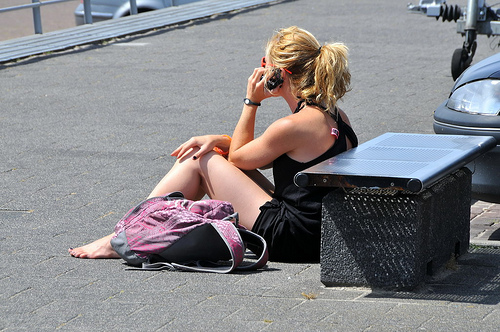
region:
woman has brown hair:
[254, 27, 365, 114]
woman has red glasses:
[250, 55, 294, 85]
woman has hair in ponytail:
[307, 42, 365, 135]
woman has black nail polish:
[170, 122, 227, 167]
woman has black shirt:
[252, 102, 353, 211]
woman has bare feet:
[49, 148, 180, 265]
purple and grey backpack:
[130, 177, 260, 279]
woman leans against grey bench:
[303, 117, 493, 309]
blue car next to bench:
[432, 52, 498, 177]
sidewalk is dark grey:
[25, 15, 257, 125]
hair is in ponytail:
[305, 40, 345, 94]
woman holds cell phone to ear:
[229, 62, 311, 102]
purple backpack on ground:
[113, 164, 291, 294]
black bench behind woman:
[330, 98, 471, 310]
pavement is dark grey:
[0, 60, 192, 217]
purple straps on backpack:
[185, 171, 272, 294]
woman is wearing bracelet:
[236, 85, 253, 124]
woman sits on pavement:
[143, 32, 378, 274]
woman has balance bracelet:
[225, 81, 268, 122]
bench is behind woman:
[287, 122, 467, 329]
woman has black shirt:
[303, 79, 363, 197]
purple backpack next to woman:
[126, 184, 258, 285]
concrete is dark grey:
[0, 88, 127, 247]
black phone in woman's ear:
[263, 70, 296, 97]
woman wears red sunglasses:
[255, 56, 295, 100]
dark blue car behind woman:
[407, 53, 499, 199]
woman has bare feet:
[70, 140, 255, 282]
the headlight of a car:
[445, 80, 499, 115]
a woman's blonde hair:
[264, 22, 354, 107]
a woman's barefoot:
[66, 234, 116, 260]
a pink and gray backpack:
[108, 188, 268, 275]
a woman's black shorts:
[248, 200, 309, 256]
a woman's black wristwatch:
[243, 93, 259, 108]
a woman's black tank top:
[263, 105, 358, 207]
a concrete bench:
[294, 124, 491, 288]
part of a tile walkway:
[0, 57, 204, 329]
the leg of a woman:
[127, 143, 265, 227]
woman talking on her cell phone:
[68, 26, 364, 261]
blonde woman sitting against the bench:
[66, 25, 360, 260]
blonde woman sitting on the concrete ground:
[68, 27, 362, 261]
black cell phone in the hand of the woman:
[255, 66, 285, 87]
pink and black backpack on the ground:
[109, 190, 266, 270]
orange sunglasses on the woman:
[261, 55, 294, 76]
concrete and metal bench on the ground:
[293, 132, 497, 289]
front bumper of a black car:
[433, 55, 499, 202]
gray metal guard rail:
[0, 0, 185, 45]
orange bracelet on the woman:
[212, 132, 234, 155]